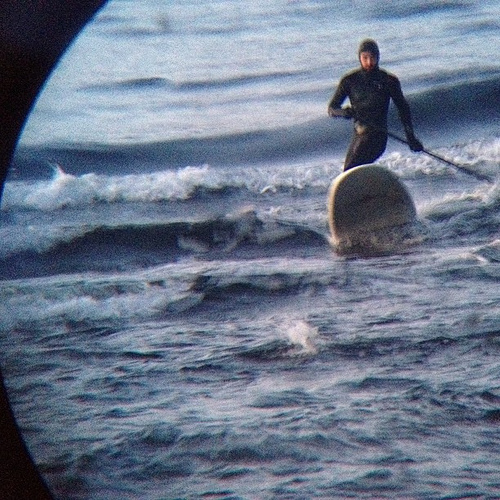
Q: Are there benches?
A: No, there are no benches.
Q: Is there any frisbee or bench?
A: No, there are no benches or frisbees.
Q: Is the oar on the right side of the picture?
A: Yes, the oar is on the right of the image.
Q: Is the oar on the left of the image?
A: No, the oar is on the right of the image.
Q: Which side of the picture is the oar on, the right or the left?
A: The oar is on the right of the image.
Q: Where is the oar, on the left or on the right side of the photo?
A: The oar is on the right of the image.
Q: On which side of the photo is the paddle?
A: The paddle is on the right of the image.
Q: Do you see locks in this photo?
A: No, there are no locks.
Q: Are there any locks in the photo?
A: No, there are no locks.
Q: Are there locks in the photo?
A: No, there are no locks.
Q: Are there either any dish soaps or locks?
A: No, there are no locks or dish soaps.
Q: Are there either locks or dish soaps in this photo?
A: No, there are no locks or dish soaps.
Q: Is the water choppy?
A: Yes, the water is choppy.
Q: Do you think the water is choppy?
A: Yes, the water is choppy.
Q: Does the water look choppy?
A: Yes, the water is choppy.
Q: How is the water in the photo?
A: The water is choppy.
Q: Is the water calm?
A: No, the water is choppy.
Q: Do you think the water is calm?
A: No, the water is choppy.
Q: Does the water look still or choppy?
A: The water is choppy.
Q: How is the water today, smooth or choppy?
A: The water is choppy.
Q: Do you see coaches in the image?
A: No, there are no coaches.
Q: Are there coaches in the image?
A: No, there are no coaches.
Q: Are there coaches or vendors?
A: No, there are no coaches or vendors.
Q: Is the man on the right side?
A: Yes, the man is on the right of the image.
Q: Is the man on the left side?
A: No, the man is on the right of the image.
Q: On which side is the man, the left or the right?
A: The man is on the right of the image.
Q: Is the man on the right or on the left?
A: The man is on the right of the image.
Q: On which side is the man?
A: The man is on the right of the image.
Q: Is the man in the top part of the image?
A: Yes, the man is in the top of the image.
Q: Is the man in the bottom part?
A: No, the man is in the top of the image.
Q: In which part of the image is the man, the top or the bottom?
A: The man is in the top of the image.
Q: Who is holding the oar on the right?
A: The man is holding the oar.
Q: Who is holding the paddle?
A: The man is holding the oar.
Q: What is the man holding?
A: The man is holding the oar.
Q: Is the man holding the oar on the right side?
A: Yes, the man is holding the paddle.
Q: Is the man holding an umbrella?
A: No, the man is holding the paddle.